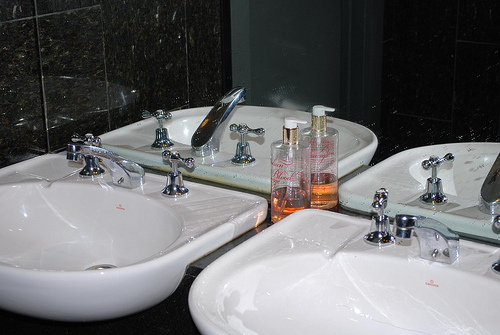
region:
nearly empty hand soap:
[268, 116, 313, 221]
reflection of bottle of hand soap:
[301, 104, 340, 208]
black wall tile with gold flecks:
[4, 2, 46, 166]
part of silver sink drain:
[85, 263, 114, 270]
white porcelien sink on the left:
[1, 150, 267, 320]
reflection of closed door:
[246, 4, 339, 114]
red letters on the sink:
[423, 277, 438, 289]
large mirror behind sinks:
[36, 5, 495, 243]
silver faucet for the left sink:
[66, 144, 144, 186]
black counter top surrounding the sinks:
[1, 152, 494, 332]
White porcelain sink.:
[190, 208, 497, 333]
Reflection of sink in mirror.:
[87, 81, 378, 180]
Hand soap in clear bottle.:
[267, 119, 312, 224]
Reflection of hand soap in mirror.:
[307, 104, 342, 209]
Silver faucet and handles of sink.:
[57, 134, 191, 199]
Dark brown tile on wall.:
[4, 8, 177, 133]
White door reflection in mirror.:
[225, 0, 407, 123]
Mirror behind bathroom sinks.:
[37, 0, 493, 160]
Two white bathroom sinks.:
[5, 148, 495, 329]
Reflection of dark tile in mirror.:
[383, 7, 498, 137]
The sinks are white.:
[0, 140, 493, 332]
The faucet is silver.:
[351, 188, 466, 270]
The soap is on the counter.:
[260, 110, 320, 225]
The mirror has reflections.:
[36, 3, 498, 255]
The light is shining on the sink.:
[8, 3, 479, 333]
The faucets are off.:
[60, 135, 492, 273]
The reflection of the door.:
[228, 2, 392, 153]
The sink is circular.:
[7, 133, 222, 333]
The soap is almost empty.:
[264, 124, 310, 223]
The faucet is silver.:
[354, 182, 395, 245]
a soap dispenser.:
[261, 112, 313, 222]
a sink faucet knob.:
[144, 128, 206, 208]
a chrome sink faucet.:
[79, 142, 151, 192]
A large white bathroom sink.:
[0, 143, 267, 330]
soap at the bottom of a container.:
[266, 180, 316, 228]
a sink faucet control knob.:
[361, 185, 398, 243]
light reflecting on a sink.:
[14, 192, 36, 232]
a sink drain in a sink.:
[79, 250, 123, 280]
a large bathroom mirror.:
[33, 0, 498, 248]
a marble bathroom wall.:
[0, 0, 58, 174]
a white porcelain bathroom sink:
[185, 205, 498, 332]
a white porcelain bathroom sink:
[0, 150, 268, 320]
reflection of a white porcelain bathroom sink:
[331, 140, 497, 242]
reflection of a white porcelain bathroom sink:
[71, 100, 372, 190]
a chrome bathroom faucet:
[392, 212, 459, 264]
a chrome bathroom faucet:
[59, 138, 144, 189]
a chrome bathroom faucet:
[188, 84, 248, 156]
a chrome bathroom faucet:
[475, 152, 498, 214]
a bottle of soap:
[267, 117, 307, 223]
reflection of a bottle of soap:
[302, 103, 337, 207]